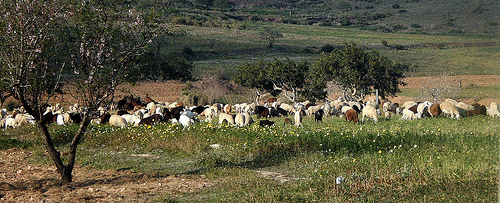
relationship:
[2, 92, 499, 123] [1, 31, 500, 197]
sheep in field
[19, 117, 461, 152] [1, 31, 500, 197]
flowers in field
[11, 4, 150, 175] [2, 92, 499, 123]
tree next to sheep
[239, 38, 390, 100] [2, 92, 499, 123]
trees behind sheep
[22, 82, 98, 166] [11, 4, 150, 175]
branches of tree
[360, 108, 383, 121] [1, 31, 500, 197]
sheep in field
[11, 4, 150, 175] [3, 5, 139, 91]
tree with flowers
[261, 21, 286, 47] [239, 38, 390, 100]
tree behind trees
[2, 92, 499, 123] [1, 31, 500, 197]
sheep laying in field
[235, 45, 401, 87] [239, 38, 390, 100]
tops of trees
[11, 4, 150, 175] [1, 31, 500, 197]
tree in field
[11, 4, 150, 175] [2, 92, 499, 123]
tree in front of sheep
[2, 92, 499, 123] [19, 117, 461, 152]
sheep beside flowers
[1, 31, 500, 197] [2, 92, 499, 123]
field with sheep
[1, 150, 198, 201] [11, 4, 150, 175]
dirt around tree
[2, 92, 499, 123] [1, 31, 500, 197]
sheep are eating in field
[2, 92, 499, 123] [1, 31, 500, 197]
sheep grazing on field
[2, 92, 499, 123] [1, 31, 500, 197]
sheep grazing in field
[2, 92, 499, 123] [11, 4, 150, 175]
sheep behind tree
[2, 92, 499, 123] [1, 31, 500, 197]
sheep standing in field